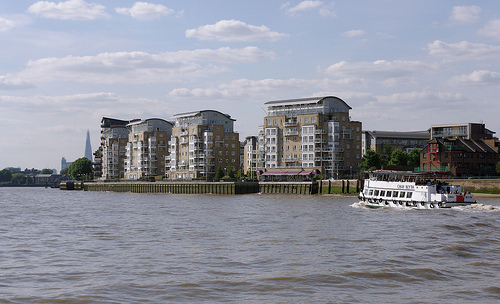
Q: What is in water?
A: Boat.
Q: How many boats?
A: One.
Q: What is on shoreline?
A: Buildings.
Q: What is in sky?
A: Clouds.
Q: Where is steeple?
A: In background, left.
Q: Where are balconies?
A: On buildings.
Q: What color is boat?
A: White.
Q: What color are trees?
A: Green.